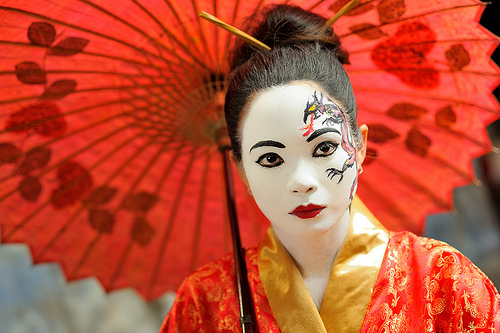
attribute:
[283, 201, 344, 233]
lips — red, painted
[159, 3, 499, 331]
woman — pretty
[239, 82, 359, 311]
face makeup — white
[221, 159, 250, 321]
pole — black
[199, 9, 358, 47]
chopsticks — brown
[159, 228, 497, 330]
red outfit — gold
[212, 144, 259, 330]
handle — black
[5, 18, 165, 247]
decorations — leaves 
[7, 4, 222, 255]
umbrella — red, big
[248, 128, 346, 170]
eyes — dark, painted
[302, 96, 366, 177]
dragon — black, red, yellow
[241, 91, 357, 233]
face — white, painted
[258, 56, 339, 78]
hair — brown, dark, up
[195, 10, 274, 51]
stick — brown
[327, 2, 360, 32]
stick — brown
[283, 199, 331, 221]
lips — bright, red, painted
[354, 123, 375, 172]
ear — small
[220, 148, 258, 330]
handle — black, shiney, long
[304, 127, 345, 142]
eyebrow — painted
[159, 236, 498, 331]
kimono — gold, red, silky, pretty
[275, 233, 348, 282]
neck — painted, white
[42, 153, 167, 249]
leaves — black, printed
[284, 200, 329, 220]
lips — bright red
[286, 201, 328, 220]
lipstick — bright red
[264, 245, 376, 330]
collar — yellow, gold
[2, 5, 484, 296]
umbrella — red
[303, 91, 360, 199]
dragon — painted